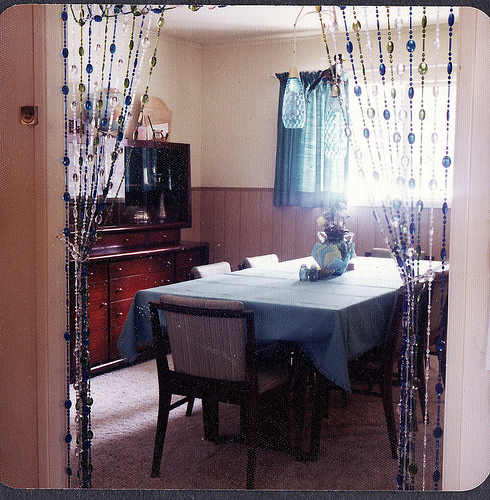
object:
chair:
[144, 300, 302, 489]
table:
[138, 237, 443, 462]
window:
[346, 87, 458, 201]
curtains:
[272, 68, 353, 211]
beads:
[340, 117, 450, 206]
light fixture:
[280, 8, 307, 130]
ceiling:
[110, 3, 469, 45]